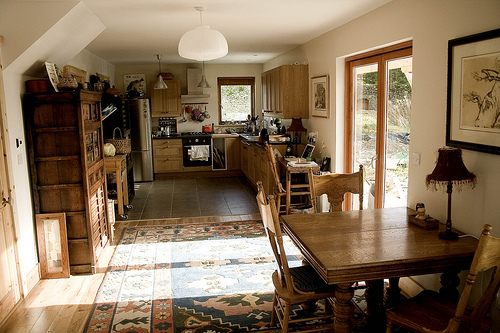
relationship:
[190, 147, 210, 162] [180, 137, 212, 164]
towel draped over door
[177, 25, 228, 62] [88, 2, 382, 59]
light hanging from ceiling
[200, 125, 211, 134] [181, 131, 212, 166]
pot on stove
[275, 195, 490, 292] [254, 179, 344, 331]
table has chair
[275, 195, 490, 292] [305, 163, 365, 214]
table has chair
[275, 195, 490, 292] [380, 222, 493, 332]
table has chair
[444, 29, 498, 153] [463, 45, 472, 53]
painting has matting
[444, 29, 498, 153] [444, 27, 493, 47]
painting has frame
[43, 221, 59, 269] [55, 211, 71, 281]
mirror has frame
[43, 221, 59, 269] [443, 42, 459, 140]
mirror has frame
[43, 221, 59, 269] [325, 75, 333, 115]
mirror has frame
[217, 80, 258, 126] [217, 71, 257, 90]
kitchen window has framing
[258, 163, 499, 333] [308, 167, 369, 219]
table has chairs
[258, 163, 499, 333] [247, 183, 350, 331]
table has chairs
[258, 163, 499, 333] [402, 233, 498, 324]
table has chairs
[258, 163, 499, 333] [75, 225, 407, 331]
table on carpet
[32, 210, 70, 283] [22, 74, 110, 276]
picture leaning against cabinet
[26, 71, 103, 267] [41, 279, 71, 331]
cabinet on floor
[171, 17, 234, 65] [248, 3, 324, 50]
light on ceiling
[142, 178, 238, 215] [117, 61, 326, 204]
tile in kitchen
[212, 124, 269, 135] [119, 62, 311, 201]
counter in kitchen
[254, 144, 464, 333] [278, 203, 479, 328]
dining table a wooden table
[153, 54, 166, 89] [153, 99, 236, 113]
silver light fixtures on ceiling